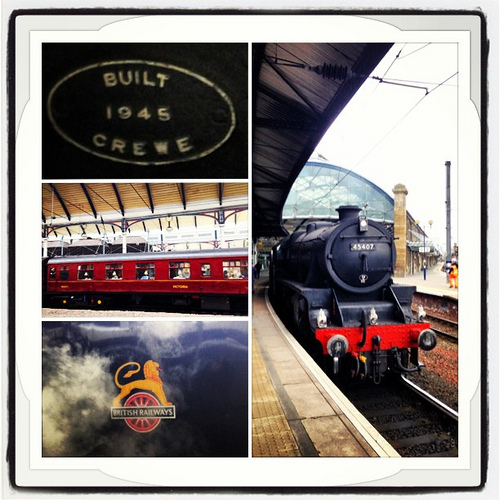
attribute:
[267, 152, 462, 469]
station — outdoors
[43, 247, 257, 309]
train — red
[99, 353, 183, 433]
lion — yellow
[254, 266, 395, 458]
platform — tan, black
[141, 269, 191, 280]
people — passengers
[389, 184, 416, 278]
pillar — concrete